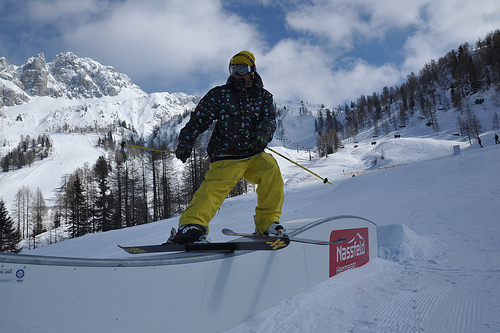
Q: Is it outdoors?
A: Yes, it is outdoors.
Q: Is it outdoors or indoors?
A: It is outdoors.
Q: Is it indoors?
A: No, it is outdoors.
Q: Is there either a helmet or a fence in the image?
A: No, there are no helmets or fences.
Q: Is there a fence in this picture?
A: No, there are no fences.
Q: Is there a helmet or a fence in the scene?
A: No, there are no fences or helmets.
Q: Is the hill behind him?
A: Yes, the hill is behind a man.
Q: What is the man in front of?
A: The man is in front of the hill.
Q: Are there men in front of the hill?
A: Yes, there is a man in front of the hill.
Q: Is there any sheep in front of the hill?
A: No, there is a man in front of the hill.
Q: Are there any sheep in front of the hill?
A: No, there is a man in front of the hill.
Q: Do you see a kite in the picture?
A: No, there are no kites.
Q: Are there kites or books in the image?
A: No, there are no kites or books.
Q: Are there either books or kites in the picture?
A: No, there are no kites or books.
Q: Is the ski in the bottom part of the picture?
A: Yes, the ski is in the bottom of the image.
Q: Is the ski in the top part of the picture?
A: No, the ski is in the bottom of the image.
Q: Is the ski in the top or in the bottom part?
A: The ski is in the bottom of the image.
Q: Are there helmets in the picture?
A: No, there are no helmets.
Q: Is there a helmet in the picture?
A: No, there are no helmets.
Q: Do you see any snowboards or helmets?
A: No, there are no helmets or snowboards.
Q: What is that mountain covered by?
A: The mountain is covered by the snow.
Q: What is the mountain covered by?
A: The mountain is covered by the snow.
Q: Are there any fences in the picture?
A: No, there are no fences.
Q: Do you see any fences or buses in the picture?
A: No, there are no fences or buses.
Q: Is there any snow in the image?
A: Yes, there is snow.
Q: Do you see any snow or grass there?
A: Yes, there is snow.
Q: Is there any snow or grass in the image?
A: Yes, there is snow.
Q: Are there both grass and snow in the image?
A: No, there is snow but no grass.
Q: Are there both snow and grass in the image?
A: No, there is snow but no grass.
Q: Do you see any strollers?
A: No, there are no strollers.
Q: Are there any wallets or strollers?
A: No, there are no strollers or wallets.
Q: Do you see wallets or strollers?
A: No, there are no strollers or wallets.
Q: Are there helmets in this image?
A: No, there are no helmets.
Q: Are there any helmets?
A: No, there are no helmets.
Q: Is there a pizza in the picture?
A: Yes, there is a pizza.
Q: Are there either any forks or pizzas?
A: Yes, there is a pizza.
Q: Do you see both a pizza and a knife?
A: No, there is a pizza but no knives.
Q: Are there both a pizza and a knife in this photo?
A: No, there is a pizza but no knives.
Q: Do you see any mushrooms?
A: No, there are no mushrooms.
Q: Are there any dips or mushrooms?
A: No, there are no mushrooms or dips.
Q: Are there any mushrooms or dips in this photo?
A: No, there are no mushrooms or dips.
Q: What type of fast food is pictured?
A: The fast food is a pizza.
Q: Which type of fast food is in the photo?
A: The fast food is a pizza.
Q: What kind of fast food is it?
A: The food is a pizza.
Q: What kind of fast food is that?
A: This is a pizza.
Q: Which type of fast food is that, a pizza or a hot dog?
A: This is a pizza.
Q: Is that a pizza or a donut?
A: That is a pizza.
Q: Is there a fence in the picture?
A: No, there are no fences.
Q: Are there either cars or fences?
A: No, there are no fences or cars.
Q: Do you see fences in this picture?
A: No, there are no fences.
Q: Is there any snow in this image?
A: Yes, there is snow.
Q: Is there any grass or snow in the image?
A: Yes, there is snow.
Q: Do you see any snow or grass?
A: Yes, there is snow.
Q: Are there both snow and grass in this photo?
A: No, there is snow but no grass.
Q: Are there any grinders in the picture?
A: No, there are no grinders.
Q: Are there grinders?
A: No, there are no grinders.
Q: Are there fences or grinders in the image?
A: No, there are no grinders or fences.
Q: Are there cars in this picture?
A: No, there are no cars.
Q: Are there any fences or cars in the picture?
A: No, there are no cars or fences.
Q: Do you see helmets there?
A: No, there are no helmets.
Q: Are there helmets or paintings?
A: No, there are no helmets or paintings.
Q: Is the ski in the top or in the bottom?
A: The ski is in the bottom of the image.